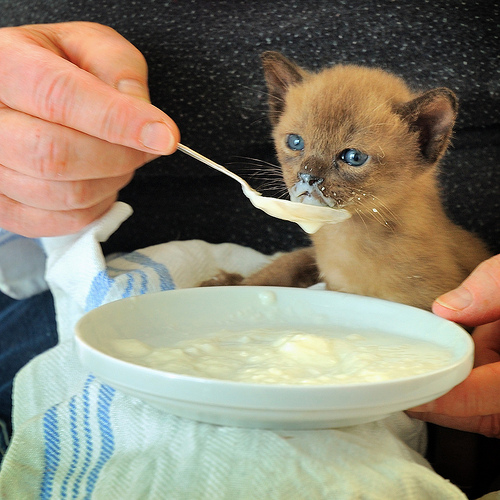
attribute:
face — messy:
[278, 129, 379, 206]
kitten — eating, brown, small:
[258, 49, 500, 311]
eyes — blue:
[286, 134, 373, 170]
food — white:
[111, 329, 458, 392]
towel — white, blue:
[1, 342, 472, 500]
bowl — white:
[72, 284, 483, 435]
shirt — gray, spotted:
[1, 1, 500, 260]